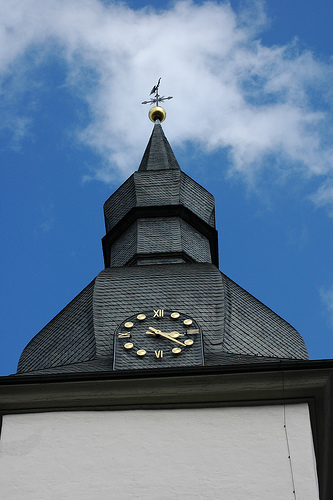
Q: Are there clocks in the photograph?
A: Yes, there is a clock.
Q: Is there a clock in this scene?
A: Yes, there is a clock.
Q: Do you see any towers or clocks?
A: Yes, there is a clock.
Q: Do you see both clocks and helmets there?
A: No, there is a clock but no helmets.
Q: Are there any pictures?
A: No, there are no pictures.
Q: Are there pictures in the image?
A: No, there are no pictures.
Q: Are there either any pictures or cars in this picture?
A: No, there are no pictures or cars.